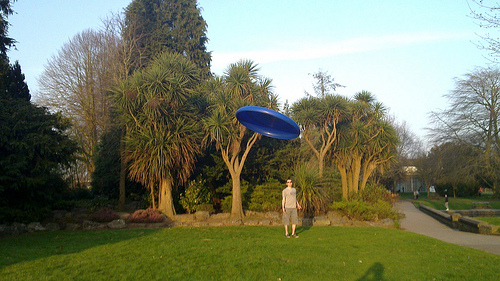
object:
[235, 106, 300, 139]
frisbee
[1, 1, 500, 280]
air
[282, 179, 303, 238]
man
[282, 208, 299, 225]
shorts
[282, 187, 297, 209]
shirt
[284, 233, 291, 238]
shoe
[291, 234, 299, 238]
shoe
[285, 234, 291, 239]
foot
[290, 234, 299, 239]
foot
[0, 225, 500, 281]
grass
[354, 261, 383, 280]
shadow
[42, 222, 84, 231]
bed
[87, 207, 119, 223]
bed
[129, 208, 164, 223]
bed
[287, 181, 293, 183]
sunglasses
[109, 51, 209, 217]
tree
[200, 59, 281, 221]
tree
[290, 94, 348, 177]
tree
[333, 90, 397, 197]
tree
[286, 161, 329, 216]
tree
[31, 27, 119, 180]
tree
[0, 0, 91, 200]
tree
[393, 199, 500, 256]
sidewalk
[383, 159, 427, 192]
residence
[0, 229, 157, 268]
shadow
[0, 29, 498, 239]
background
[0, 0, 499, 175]
sky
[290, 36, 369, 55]
cloud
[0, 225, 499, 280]
patch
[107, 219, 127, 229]
rock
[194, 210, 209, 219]
rock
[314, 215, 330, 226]
rock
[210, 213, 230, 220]
rock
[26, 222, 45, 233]
rock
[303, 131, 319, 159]
branch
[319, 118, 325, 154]
branch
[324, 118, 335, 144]
branch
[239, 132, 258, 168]
branch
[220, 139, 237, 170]
branch